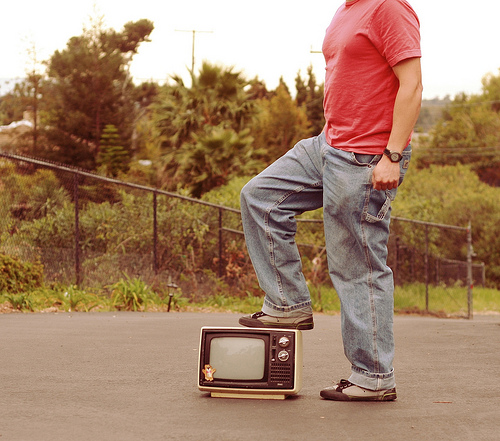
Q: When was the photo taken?
A: Daytime.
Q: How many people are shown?
A: One.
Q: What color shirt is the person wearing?
A: Red.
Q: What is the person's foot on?
A: TV.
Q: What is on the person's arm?
A: Watch.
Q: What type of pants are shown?
A: Jeans.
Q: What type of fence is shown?
A: Metal.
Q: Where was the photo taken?
A: On blacktop outside.